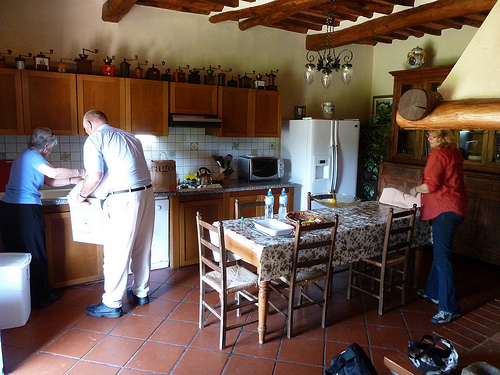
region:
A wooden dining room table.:
[209, 194, 433, 339]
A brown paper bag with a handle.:
[149, 150, 180, 192]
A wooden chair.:
[195, 216, 271, 346]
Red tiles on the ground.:
[0, 229, 499, 372]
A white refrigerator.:
[294, 117, 361, 204]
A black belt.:
[103, 186, 153, 196]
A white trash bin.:
[0, 252, 33, 333]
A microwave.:
[241, 150, 288, 185]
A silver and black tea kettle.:
[194, 166, 212, 184]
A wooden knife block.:
[212, 166, 234, 187]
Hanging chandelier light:
[302, 12, 353, 90]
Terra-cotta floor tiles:
[30, 336, 213, 371]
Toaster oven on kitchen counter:
[235, 152, 287, 184]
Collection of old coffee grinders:
[3, 44, 286, 94]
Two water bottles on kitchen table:
[260, 185, 288, 221]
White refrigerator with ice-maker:
[285, 110, 355, 207]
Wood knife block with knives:
[215, 167, 233, 186]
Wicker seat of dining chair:
[195, 265, 255, 293]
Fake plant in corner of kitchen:
[358, 92, 388, 203]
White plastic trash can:
[0, 251, 35, 333]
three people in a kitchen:
[7, 108, 466, 327]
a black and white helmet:
[403, 328, 458, 374]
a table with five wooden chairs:
[195, 191, 427, 344]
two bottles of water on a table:
[265, 190, 288, 220]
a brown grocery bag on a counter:
[146, 150, 176, 192]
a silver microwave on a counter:
[241, 153, 286, 183]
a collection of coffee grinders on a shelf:
[3, 45, 278, 89]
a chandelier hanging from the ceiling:
[303, 10, 355, 90]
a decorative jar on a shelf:
[405, 45, 428, 70]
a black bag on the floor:
[324, 338, 375, 373]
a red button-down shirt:
[421, 147, 464, 218]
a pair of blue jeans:
[428, 215, 451, 307]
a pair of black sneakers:
[85, 298, 149, 318]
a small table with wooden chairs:
[198, 211, 423, 348]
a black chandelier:
[294, 13, 364, 90]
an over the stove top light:
[166, 113, 226, 133]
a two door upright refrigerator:
[289, 115, 357, 201]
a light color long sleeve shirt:
[82, 125, 151, 191]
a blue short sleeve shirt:
[10, 155, 43, 205]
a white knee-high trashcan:
[0, 251, 35, 330]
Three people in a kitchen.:
[11, 83, 479, 324]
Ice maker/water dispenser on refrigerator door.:
[304, 150, 333, 186]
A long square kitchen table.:
[191, 193, 446, 344]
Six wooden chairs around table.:
[183, 185, 437, 350]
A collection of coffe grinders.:
[6, 54, 284, 91]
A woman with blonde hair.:
[393, 115, 473, 247]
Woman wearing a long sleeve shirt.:
[410, 123, 472, 230]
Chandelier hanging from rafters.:
[285, 7, 360, 90]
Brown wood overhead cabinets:
[3, 75, 278, 142]